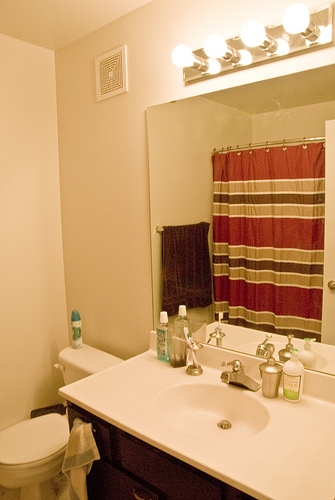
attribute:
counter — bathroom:
[50, 311, 333, 497]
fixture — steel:
[220, 358, 260, 390]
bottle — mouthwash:
[153, 310, 176, 363]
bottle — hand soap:
[279, 344, 305, 404]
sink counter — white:
[88, 360, 313, 499]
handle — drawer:
[88, 422, 101, 437]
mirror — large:
[143, 60, 333, 377]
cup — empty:
[162, 323, 191, 367]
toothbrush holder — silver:
[185, 334, 199, 378]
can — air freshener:
[69, 308, 82, 348]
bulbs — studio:
[153, 4, 324, 73]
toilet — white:
[0, 324, 118, 485]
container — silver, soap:
[279, 345, 303, 401]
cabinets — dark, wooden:
[58, 410, 173, 498]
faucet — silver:
[217, 359, 261, 391]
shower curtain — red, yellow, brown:
[209, 136, 334, 345]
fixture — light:
[163, 9, 321, 82]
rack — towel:
[159, 227, 166, 234]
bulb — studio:
[168, 35, 200, 78]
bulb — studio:
[201, 24, 243, 66]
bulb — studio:
[271, 7, 320, 48]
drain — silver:
[218, 412, 234, 433]